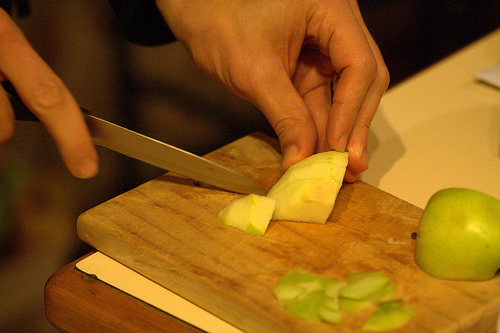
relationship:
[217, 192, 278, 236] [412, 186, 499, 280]
sliced piece of an apple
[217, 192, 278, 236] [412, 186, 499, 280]
piece of an apple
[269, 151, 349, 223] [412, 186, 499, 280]
piece of an apple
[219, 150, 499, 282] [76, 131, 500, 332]
apple on top of cutting board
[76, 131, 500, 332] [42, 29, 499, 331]
cutting board on top of table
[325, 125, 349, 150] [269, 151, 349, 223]
finger tip on apple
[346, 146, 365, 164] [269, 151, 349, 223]
finger tip on apple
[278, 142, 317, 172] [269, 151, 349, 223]
finger tip on apple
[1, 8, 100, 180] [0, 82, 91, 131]
hand on top of knife handle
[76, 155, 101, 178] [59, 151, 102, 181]
nail on finger tip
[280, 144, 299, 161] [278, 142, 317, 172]
nail on finger tip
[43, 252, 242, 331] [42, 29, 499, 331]
corner of table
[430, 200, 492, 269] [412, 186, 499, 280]
light reflection on top of apple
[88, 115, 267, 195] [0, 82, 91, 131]
silver knife with handle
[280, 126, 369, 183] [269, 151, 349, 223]
fingers holding food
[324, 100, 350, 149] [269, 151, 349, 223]
finger holding food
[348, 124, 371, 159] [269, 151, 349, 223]
finger holding food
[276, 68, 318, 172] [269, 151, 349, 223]
finger holding food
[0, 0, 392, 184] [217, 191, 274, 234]
person cutting apple slicings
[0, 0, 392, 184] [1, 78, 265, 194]
person cutting with a knife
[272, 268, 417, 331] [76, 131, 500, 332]
peel on top of cutting board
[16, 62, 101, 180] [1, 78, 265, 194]
finger holding knife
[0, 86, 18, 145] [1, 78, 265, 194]
finger holding knife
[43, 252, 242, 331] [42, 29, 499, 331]
corner of counter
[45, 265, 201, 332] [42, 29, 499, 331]
wooden edge of counter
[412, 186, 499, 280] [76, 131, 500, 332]
apple on top of a cutting board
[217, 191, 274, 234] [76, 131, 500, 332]
apple slicings on top of a cutting board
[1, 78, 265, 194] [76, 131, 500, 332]
knife on top of a cutting board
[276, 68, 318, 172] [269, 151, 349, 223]
thumb on top of an apple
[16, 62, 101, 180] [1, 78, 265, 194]
pointer finger on a knife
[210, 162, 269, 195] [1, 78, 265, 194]
tip of a knife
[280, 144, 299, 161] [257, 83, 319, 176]
finger nail on a thumb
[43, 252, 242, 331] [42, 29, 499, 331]
corner of a counter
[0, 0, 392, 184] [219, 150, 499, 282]
person cutting an apple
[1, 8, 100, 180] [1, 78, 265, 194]
hand holding knife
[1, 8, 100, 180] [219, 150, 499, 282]
hand cutting an apple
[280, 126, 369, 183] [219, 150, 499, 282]
fingers holding an apple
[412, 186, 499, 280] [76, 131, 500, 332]
apple on top of cutting board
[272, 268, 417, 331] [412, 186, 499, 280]
peel of an apple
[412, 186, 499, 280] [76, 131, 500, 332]
part of apple on top of cutting board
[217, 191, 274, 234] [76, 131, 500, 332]
apple slicings on top of cutting board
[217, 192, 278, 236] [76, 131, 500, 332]
slice of apple on top of cutting board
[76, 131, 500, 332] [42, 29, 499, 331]
cutting board on top of countertop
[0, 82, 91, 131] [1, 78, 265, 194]
handle on knife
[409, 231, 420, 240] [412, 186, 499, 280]
stem on an apple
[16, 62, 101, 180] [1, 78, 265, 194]
finger gripping cutting knife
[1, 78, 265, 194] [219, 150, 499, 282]
knife cutting into an apple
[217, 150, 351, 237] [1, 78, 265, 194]
apple slicings have been knifed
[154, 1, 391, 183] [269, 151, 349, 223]
hand holding an apple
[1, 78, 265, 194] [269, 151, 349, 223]
knife slicing into an apple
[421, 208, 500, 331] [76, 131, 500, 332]
corner of wooden cutting board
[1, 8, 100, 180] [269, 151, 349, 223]
hand cutting an apple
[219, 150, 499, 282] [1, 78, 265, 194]
apple cut with knife handle